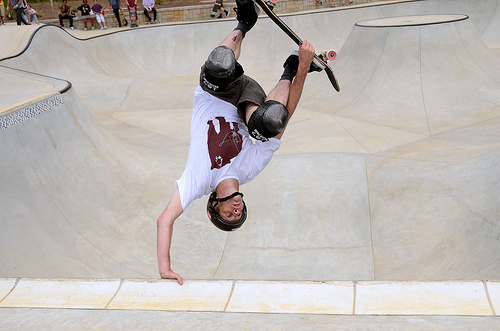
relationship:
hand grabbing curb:
[160, 272, 179, 282] [188, 280, 281, 283]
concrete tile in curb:
[27, 284, 96, 301] [188, 280, 281, 283]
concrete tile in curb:
[135, 286, 216, 304] [188, 280, 281, 283]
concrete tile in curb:
[246, 291, 341, 311] [188, 280, 281, 283]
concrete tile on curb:
[381, 291, 470, 307] [188, 280, 281, 283]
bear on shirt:
[206, 115, 243, 170] [193, 104, 268, 184]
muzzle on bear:
[233, 132, 237, 136] [206, 115, 243, 170]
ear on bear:
[212, 166, 215, 171] [206, 115, 243, 170]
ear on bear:
[230, 162, 231, 165] [206, 115, 243, 170]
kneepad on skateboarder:
[214, 52, 231, 73] [154, 0, 340, 285]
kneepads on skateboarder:
[200, 44, 292, 144] [154, 0, 340, 285]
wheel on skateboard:
[324, 52, 343, 60] [279, 20, 290, 30]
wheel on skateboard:
[271, 0, 277, 4] [279, 20, 290, 30]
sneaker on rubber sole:
[241, 3, 251, 20] [257, 9, 259, 12]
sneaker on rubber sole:
[289, 58, 297, 68] [294, 50, 295, 53]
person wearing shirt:
[94, 1, 101, 3] [94, 4, 100, 10]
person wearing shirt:
[128, 0, 133, 4] [193, 104, 268, 184]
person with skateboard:
[94, 1, 101, 3] [129, 8, 137, 19]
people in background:
[7, 2, 38, 22] [169, 2, 193, 6]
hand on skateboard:
[298, 40, 317, 67] [279, 20, 290, 30]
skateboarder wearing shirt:
[154, 0, 340, 285] [175, 82, 282, 209]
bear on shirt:
[206, 115, 243, 168] [175, 82, 282, 209]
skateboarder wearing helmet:
[154, 0, 340, 285] [206, 189, 249, 232]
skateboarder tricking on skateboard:
[154, 0, 340, 285] [209, 0, 348, 86]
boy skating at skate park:
[155, 2, 315, 282] [4, 1, 496, 327]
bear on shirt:
[206, 115, 243, 168] [174, 83, 283, 213]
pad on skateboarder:
[195, 38, 235, 104] [154, 0, 340, 285]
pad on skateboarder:
[251, 98, 291, 151] [154, 0, 340, 285]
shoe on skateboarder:
[226, 3, 263, 34] [154, 0, 340, 285]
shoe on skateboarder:
[272, 46, 323, 73] [154, 0, 340, 285]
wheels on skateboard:
[321, 47, 337, 62] [254, 2, 339, 93]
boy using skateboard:
[155, 2, 315, 282] [254, 2, 339, 93]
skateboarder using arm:
[154, 0, 340, 285] [143, 197, 176, 276]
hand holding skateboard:
[295, 40, 316, 68] [254, 2, 339, 93]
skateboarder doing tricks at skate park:
[156, 0, 343, 285] [4, 1, 496, 327]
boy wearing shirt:
[155, 2, 315, 282] [175, 82, 282, 209]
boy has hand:
[155, 1, 324, 286] [157, 264, 184, 284]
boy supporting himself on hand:
[155, 1, 324, 286] [157, 264, 184, 284]